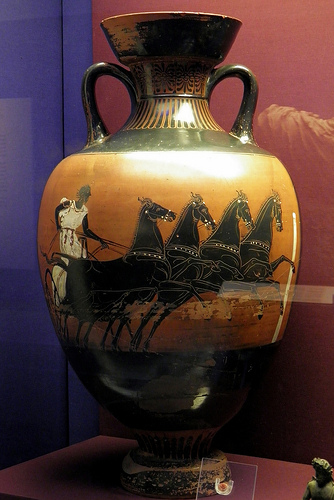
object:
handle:
[204, 62, 260, 147]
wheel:
[43, 266, 63, 335]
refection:
[188, 384, 210, 412]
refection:
[172, 99, 198, 126]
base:
[120, 446, 234, 500]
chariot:
[43, 251, 163, 345]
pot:
[36, 10, 303, 496]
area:
[129, 363, 206, 412]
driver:
[50, 184, 110, 309]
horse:
[237, 190, 298, 323]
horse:
[197, 187, 274, 325]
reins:
[98, 237, 132, 251]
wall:
[60, 0, 333, 469]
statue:
[302, 455, 333, 499]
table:
[0, 433, 333, 500]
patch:
[134, 348, 172, 407]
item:
[213, 477, 234, 497]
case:
[194, 456, 258, 499]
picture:
[256, 101, 333, 166]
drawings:
[38, 181, 297, 357]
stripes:
[124, 249, 164, 264]